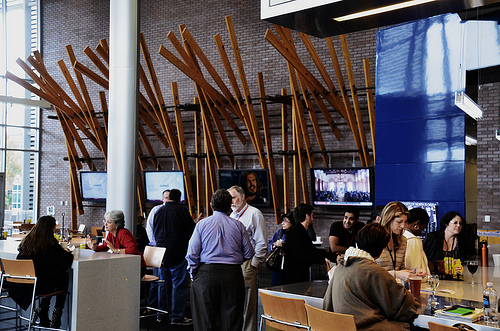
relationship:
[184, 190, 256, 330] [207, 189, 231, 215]
man has hair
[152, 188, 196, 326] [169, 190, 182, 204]
man has hair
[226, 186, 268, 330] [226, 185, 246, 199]
man has hair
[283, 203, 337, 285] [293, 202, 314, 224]
man has hair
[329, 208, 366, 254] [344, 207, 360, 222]
man has hair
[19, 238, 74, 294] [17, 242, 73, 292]
woman has shirt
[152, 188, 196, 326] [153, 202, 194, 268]
man has shirt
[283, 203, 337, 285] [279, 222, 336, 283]
man has shirt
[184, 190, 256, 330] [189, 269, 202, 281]
man has hand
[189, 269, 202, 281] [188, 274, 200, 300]
hand in pocket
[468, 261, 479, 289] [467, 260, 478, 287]
glass of wine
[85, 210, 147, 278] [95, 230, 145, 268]
woman wearing shirt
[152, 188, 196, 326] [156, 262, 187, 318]
man wearing jeans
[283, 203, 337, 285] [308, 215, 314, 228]
man has beard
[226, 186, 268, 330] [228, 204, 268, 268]
man wearing dress shirt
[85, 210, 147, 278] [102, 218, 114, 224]
woman wearing glasses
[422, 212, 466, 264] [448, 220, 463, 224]
woman wearing glasses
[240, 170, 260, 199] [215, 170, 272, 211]
man on television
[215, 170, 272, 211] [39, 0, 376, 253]
television on wall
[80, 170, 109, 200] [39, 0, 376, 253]
television on wall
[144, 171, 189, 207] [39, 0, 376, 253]
television on wall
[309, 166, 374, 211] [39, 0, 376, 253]
television on wall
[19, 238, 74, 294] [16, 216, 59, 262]
woman has hair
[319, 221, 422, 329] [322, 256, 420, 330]
woman wearing coat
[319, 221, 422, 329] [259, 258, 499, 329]
woman at desk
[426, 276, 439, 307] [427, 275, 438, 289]
glass of water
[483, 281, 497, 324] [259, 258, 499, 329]
water bottle on desk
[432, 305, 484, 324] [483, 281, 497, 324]
book near water bottle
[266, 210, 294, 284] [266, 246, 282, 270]
woman has bag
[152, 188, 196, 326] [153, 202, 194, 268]
man wearing shirt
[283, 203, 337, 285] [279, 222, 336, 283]
man wearing shirt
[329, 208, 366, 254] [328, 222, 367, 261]
man wearing shirt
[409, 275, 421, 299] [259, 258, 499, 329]
glass on desk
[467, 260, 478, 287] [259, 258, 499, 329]
wine on desk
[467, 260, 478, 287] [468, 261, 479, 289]
wine in glass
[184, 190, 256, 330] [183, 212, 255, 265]
man has shirt